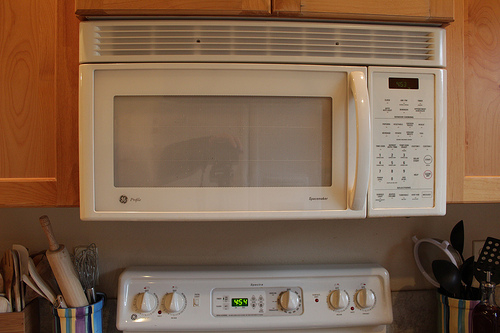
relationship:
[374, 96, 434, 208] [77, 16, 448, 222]
controls for microwave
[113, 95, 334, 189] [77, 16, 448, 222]
screen of microwave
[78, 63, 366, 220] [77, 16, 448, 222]
door of microwave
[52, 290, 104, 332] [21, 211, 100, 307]
container with kitchen utensils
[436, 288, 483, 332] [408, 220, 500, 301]
container with kitchen utensils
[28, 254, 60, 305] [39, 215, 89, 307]
spatula behind kitchen utensils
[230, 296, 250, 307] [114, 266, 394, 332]
clock on oven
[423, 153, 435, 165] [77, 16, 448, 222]
botton on microwave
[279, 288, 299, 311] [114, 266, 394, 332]
knob on oven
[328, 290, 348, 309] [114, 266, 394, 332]
knob on oven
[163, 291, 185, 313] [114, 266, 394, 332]
knob on oven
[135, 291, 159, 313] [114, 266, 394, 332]
controls on oven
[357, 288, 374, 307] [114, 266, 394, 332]
knob on oven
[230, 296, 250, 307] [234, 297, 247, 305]
clock with 4:54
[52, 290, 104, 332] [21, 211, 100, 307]
container holding kitchen utensils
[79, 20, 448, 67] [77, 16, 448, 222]
ventilation for microwave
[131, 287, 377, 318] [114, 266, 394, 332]
controls for oven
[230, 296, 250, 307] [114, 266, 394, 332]
clock on front of oven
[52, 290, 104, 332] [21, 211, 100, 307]
container full of kitchen utensils